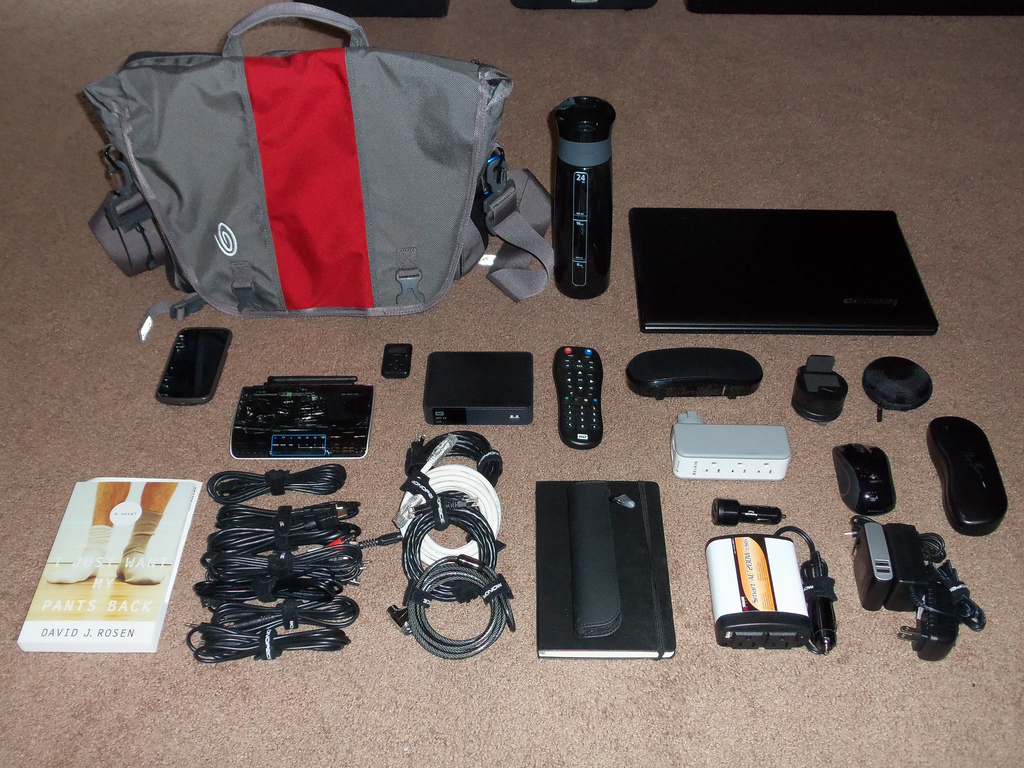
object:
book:
[16, 477, 203, 653]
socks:
[46, 509, 165, 585]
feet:
[46, 556, 164, 585]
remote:
[552, 346, 603, 451]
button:
[564, 348, 572, 354]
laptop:
[628, 207, 940, 336]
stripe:
[244, 47, 375, 311]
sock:
[46, 525, 114, 584]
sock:
[116, 510, 167, 585]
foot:
[47, 558, 103, 584]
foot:
[116, 552, 165, 585]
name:
[41, 628, 135, 637]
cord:
[404, 430, 503, 501]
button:
[585, 349, 592, 355]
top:
[18, 481, 201, 645]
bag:
[82, 1, 553, 344]